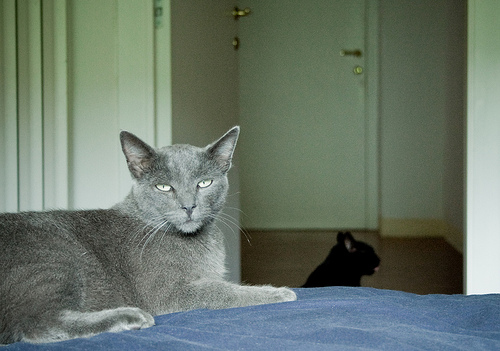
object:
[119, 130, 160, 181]
ear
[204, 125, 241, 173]
ear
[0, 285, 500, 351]
blanket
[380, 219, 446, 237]
wall trim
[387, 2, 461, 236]
wall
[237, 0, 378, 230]
door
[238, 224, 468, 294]
ground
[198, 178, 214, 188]
eye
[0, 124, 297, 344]
cat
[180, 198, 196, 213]
nose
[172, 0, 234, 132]
walls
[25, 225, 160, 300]
fur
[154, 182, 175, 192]
eye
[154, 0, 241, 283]
door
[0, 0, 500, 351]
bedroom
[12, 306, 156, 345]
cat's left/leg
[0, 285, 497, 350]
bed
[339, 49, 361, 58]
handle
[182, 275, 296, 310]
leg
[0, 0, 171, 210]
wall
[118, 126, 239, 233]
head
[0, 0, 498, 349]
scene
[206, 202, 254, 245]
whiskers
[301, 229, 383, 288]
black cat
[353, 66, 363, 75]
doorknob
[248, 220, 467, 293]
floor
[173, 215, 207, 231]
mouth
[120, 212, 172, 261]
whisker